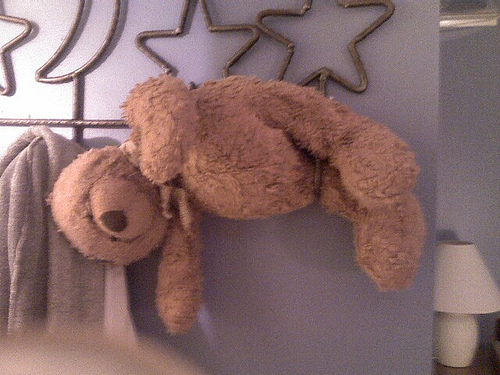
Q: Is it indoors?
A: Yes, it is indoors.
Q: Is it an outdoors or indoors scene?
A: It is indoors.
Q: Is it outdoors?
A: No, it is indoors.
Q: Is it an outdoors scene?
A: No, it is indoors.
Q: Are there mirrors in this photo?
A: No, there are no mirrors.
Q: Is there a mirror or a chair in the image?
A: No, there are no mirrors or chairs.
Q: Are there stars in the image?
A: Yes, there is a star.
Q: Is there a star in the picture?
A: Yes, there is a star.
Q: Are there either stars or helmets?
A: Yes, there is a star.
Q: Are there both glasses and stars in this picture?
A: No, there is a star but no glasses.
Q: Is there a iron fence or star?
A: Yes, there is an iron star.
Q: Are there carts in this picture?
A: No, there are no carts.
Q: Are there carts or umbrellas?
A: No, there are no carts or umbrellas.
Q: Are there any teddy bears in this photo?
A: Yes, there is a teddy bear.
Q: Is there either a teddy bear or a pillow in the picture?
A: Yes, there is a teddy bear.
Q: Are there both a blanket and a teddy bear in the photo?
A: No, there is a teddy bear but no blankets.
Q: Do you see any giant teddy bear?
A: Yes, there is a giant teddy bear.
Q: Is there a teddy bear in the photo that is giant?
A: Yes, there is a teddy bear that is giant.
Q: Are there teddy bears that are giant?
A: Yes, there is a teddy bear that is giant.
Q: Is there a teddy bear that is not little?
A: Yes, there is a giant teddy bear.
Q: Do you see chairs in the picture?
A: No, there are no chairs.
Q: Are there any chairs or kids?
A: No, there are no chairs or kids.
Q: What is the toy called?
A: The toy is a teddy bear.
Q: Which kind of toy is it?
A: The toy is a teddy bear.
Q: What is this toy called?
A: This is a teddy bear.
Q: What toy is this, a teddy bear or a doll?
A: This is a teddy bear.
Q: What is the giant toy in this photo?
A: The toy is a teddy bear.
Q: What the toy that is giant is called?
A: The toy is a teddy bear.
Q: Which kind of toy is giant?
A: The toy is a teddy bear.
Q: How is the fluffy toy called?
A: The toy is a teddy bear.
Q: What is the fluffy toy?
A: The toy is a teddy bear.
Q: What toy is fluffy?
A: The toy is a teddy bear.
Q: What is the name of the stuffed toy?
A: The toy is a teddy bear.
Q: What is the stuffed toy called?
A: The toy is a teddy bear.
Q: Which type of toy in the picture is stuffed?
A: The toy is a teddy bear.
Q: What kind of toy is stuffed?
A: The toy is a teddy bear.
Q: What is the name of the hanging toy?
A: The toy is a teddy bear.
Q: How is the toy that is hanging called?
A: The toy is a teddy bear.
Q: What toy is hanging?
A: The toy is a teddy bear.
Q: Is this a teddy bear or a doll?
A: This is a teddy bear.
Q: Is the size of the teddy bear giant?
A: Yes, the teddy bear is giant.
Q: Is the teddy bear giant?
A: Yes, the teddy bear is giant.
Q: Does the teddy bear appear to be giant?
A: Yes, the teddy bear is giant.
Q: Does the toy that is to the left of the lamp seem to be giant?
A: Yes, the teddy bear is giant.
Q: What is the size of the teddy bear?
A: The teddy bear is giant.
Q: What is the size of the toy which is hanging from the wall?
A: The teddy bear is giant.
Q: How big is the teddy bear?
A: The teddy bear is giant.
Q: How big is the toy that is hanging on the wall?
A: The teddy bear is giant.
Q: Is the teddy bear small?
A: No, the teddy bear is giant.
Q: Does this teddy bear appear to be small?
A: No, the teddy bear is giant.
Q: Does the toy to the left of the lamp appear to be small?
A: No, the teddy bear is giant.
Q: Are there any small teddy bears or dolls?
A: No, there is a teddy bear but it is giant.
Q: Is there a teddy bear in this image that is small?
A: No, there is a teddy bear but it is giant.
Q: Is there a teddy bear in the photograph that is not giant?
A: No, there is a teddy bear but it is giant.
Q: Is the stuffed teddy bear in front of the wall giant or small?
A: The teddy bear is giant.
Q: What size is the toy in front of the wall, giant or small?
A: The teddy bear is giant.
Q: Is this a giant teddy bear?
A: Yes, this is a giant teddy bear.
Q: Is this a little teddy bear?
A: No, this is a giant teddy bear.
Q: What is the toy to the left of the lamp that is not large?
A: The toy is a teddy bear.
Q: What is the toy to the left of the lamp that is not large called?
A: The toy is a teddy bear.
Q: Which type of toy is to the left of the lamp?
A: The toy is a teddy bear.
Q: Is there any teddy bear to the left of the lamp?
A: Yes, there is a teddy bear to the left of the lamp.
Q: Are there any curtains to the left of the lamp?
A: No, there is a teddy bear to the left of the lamp.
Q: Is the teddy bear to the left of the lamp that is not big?
A: Yes, the teddy bear is to the left of the lamp.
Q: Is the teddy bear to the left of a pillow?
A: No, the teddy bear is to the left of the lamp.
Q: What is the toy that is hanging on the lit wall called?
A: The toy is a teddy bear.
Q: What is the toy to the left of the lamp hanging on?
A: The teddy bear is hanging on the wall.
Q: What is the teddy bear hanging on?
A: The teddy bear is hanging on the wall.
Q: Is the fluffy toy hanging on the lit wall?
A: Yes, the teddy bear is hanging on the wall.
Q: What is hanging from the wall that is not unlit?
A: The teddy bear is hanging from the wall.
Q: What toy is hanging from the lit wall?
A: The toy is a teddy bear.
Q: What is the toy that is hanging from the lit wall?
A: The toy is a teddy bear.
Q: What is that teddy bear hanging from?
A: The teddy bear is hanging from the wall.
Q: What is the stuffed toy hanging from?
A: The teddy bear is hanging from the wall.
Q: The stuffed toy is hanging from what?
A: The teddy bear is hanging from the wall.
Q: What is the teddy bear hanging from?
A: The teddy bear is hanging from the wall.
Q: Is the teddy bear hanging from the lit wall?
A: Yes, the teddy bear is hanging from the wall.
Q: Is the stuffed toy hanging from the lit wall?
A: Yes, the teddy bear is hanging from the wall.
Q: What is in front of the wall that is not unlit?
A: The teddy bear is in front of the wall.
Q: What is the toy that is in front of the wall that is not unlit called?
A: The toy is a teddy bear.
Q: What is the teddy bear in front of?
A: The teddy bear is in front of the wall.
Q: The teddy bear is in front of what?
A: The teddy bear is in front of the wall.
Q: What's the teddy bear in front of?
A: The teddy bear is in front of the wall.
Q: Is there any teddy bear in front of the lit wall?
A: Yes, there is a teddy bear in front of the wall.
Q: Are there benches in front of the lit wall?
A: No, there is a teddy bear in front of the wall.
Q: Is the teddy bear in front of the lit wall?
A: Yes, the teddy bear is in front of the wall.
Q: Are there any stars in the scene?
A: Yes, there is a star.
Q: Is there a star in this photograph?
A: Yes, there is a star.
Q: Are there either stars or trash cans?
A: Yes, there is a star.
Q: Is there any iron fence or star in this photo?
A: Yes, there is an iron star.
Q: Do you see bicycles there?
A: No, there are no bicycles.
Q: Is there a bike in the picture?
A: No, there are no bikes.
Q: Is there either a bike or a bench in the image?
A: No, there are no bikes or benches.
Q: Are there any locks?
A: No, there are no locks.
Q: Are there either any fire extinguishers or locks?
A: No, there are no locks or fire extinguishers.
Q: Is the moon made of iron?
A: Yes, the moon is made of iron.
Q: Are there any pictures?
A: No, there are no pictures.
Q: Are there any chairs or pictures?
A: No, there are no pictures or chairs.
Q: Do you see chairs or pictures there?
A: No, there are no pictures or chairs.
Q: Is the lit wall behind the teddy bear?
A: Yes, the wall is behind the teddy bear.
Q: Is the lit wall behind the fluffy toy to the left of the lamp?
A: Yes, the wall is behind the teddy bear.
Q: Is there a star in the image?
A: Yes, there is a star.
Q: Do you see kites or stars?
A: Yes, there is a star.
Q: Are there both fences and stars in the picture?
A: No, there is a star but no fences.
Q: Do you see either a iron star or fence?
A: Yes, there is an iron star.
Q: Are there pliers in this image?
A: No, there are no pliers.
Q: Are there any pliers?
A: No, there are no pliers.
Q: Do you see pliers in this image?
A: No, there are no pliers.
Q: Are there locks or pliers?
A: No, there are no pliers or locks.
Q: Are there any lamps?
A: Yes, there is a lamp.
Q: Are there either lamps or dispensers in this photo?
A: Yes, there is a lamp.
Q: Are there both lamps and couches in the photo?
A: No, there is a lamp but no couches.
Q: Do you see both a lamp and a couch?
A: No, there is a lamp but no couches.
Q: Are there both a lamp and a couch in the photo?
A: No, there is a lamp but no couches.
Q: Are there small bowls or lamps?
A: Yes, there is a small lamp.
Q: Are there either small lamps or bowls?
A: Yes, there is a small lamp.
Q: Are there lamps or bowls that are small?
A: Yes, the lamp is small.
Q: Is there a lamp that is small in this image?
A: Yes, there is a small lamp.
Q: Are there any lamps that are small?
A: Yes, there is a lamp that is small.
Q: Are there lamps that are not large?
A: Yes, there is a small lamp.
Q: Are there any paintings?
A: No, there are no paintings.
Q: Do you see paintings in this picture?
A: No, there are no paintings.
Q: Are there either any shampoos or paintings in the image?
A: No, there are no paintings or shampoos.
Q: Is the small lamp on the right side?
A: Yes, the lamp is on the right of the image.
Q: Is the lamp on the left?
A: No, the lamp is on the right of the image.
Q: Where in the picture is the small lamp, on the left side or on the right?
A: The lamp is on the right of the image.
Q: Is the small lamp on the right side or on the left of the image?
A: The lamp is on the right of the image.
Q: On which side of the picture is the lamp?
A: The lamp is on the right of the image.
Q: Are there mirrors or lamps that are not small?
A: No, there is a lamp but it is small.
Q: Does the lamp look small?
A: Yes, the lamp is small.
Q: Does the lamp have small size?
A: Yes, the lamp is small.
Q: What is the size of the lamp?
A: The lamp is small.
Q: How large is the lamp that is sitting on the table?
A: The lamp is small.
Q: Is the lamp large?
A: No, the lamp is small.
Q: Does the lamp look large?
A: No, the lamp is small.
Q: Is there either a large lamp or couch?
A: No, there is a lamp but it is small.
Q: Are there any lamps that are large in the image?
A: No, there is a lamp but it is small.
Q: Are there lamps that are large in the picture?
A: No, there is a lamp but it is small.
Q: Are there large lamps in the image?
A: No, there is a lamp but it is small.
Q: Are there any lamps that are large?
A: No, there is a lamp but it is small.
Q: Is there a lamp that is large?
A: No, there is a lamp but it is small.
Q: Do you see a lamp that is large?
A: No, there is a lamp but it is small.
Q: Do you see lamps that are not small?
A: No, there is a lamp but it is small.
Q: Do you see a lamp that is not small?
A: No, there is a lamp but it is small.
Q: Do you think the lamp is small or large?
A: The lamp is small.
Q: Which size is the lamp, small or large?
A: The lamp is small.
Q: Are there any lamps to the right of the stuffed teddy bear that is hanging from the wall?
A: Yes, there is a lamp to the right of the teddy bear.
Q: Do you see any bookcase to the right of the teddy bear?
A: No, there is a lamp to the right of the teddy bear.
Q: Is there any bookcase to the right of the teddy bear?
A: No, there is a lamp to the right of the teddy bear.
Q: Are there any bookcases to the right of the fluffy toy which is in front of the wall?
A: No, there is a lamp to the right of the teddy bear.